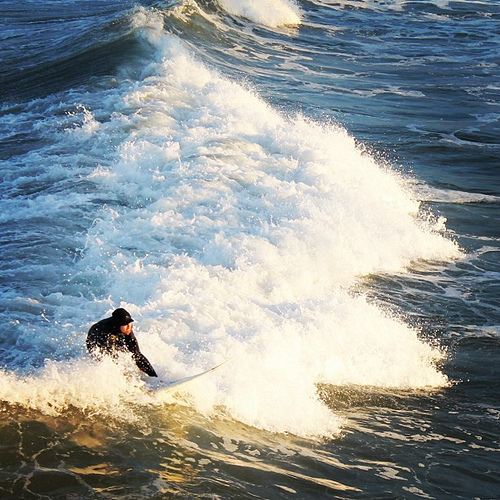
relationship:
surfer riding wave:
[71, 305, 153, 378] [157, 78, 200, 115]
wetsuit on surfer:
[89, 330, 95, 342] [71, 305, 153, 378]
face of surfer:
[118, 323, 133, 338] [71, 305, 153, 378]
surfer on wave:
[71, 305, 153, 378] [157, 78, 200, 115]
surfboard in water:
[172, 367, 207, 388] [360, 53, 476, 93]